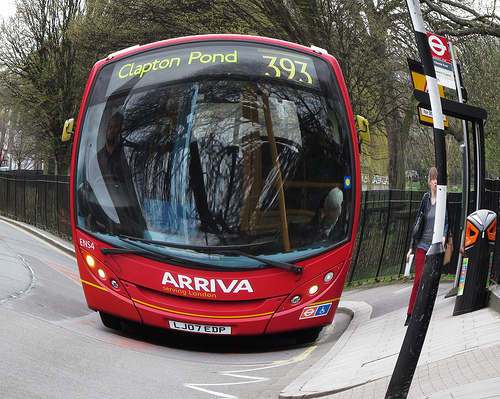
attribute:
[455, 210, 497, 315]
trash can — black, orange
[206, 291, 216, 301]
letter — yellow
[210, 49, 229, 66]
letter — yellow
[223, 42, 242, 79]
letter — yellow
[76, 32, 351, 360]
bus — red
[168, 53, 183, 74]
letter — yellow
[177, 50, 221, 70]
letter — yellow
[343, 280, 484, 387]
sidewalk — concrete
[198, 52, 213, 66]
letter — yellow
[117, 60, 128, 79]
letter — yellow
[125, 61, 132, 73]
letter — yellow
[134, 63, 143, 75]
letter — yellow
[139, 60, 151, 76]
letter — yellow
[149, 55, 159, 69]
letter — yellow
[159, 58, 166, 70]
letter — yellow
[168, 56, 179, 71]
letter — yellow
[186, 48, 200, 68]
letter — yellow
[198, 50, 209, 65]
letter — yellow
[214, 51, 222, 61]
letter — yellow